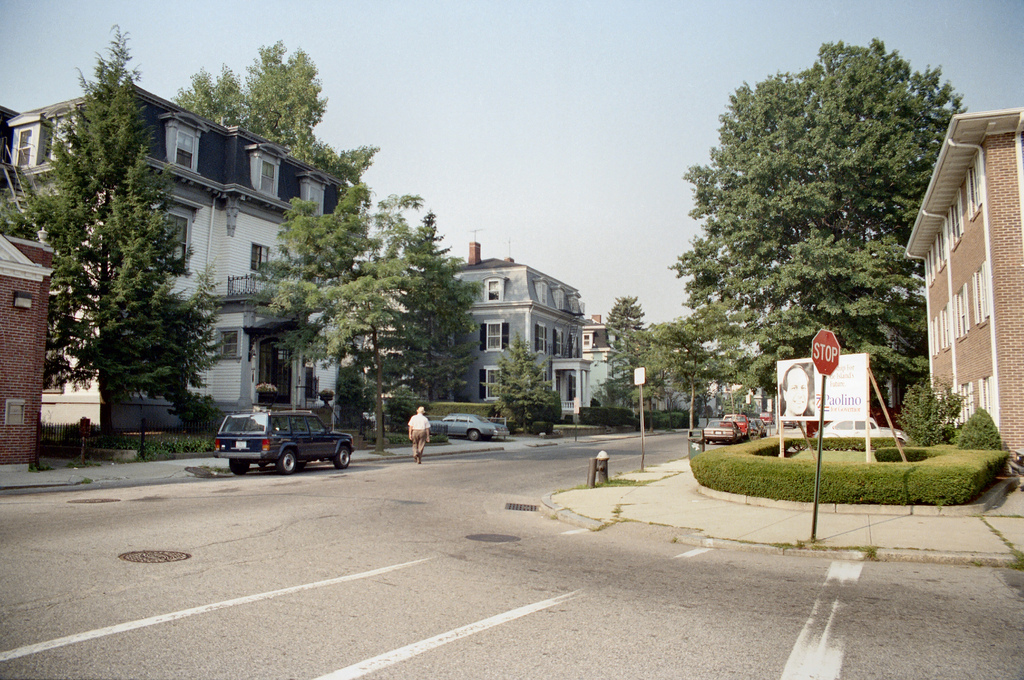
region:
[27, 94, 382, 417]
a large white house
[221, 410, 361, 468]
a blue jeep parked on the street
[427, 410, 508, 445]
a blue car parked in the driveway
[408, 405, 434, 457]
a person walking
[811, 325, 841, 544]
a stop sign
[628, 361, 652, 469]
a white street sign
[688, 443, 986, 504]
buses in front of a house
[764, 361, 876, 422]
a billboard sign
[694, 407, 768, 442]
cars parked on the side of the street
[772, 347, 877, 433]
Sign beside the building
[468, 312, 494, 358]
Black shutter on the house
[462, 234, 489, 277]
Chimney on the house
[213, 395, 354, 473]
Vehicle parked on the street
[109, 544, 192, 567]
Man hole cover in the street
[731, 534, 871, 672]
White line across the street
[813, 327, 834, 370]
a red stop sign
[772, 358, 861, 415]
a white billboard sign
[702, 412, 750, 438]
cars parked on the street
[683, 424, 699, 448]
a trash bin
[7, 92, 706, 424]
a row of houses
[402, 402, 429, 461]
a man walking on the street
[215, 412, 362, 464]
a blue jeep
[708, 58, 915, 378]
a tree in front of the house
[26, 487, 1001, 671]
the street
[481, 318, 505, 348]
a window on the house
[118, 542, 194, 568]
Manhole cover on street.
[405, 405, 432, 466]
Man walking across the street.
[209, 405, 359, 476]
Jeep parked on side of street.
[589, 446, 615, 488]
Fire hydrant near street curb.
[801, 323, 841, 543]
Stop sign at the corner of the street.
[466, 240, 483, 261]
Chimney on top of house.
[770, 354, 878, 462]
White billboard on the lawn.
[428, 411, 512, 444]
Car parked in the drivway.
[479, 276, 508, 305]
Window on the third story of the house.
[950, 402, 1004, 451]
Green bush along the side of building.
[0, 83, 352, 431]
A tall white house with upper black level.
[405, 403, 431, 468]
A man walking in white shirt on the road.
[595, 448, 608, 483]
A black hydrant with grey top.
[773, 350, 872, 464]
White sign with man's face on the side.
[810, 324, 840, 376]
Red and white STOP sign.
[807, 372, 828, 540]
A metal dark pole holding up a STOP sign.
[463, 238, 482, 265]
Brick chimney on a three story grey house.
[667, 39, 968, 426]
Large tree behind a white sign with a face on it.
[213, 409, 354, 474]
A blue parked suv.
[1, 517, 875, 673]
White lines on the street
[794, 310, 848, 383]
A red Stop sign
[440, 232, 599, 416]
A big gray house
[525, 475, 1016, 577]
The curb of a sidewalk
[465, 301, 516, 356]
A window on a house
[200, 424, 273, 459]
Two red rear lights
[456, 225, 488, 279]
Chimney on a house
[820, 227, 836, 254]
green leaves on the tree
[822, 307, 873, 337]
green leaves on the tree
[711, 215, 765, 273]
green leaves on the tree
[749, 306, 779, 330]
green leaves on the tree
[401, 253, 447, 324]
green leaves on the tree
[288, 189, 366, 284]
green leaves on the tree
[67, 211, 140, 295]
green leaves on the tree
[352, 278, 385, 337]
green leaves on the tree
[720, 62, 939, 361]
a large tree